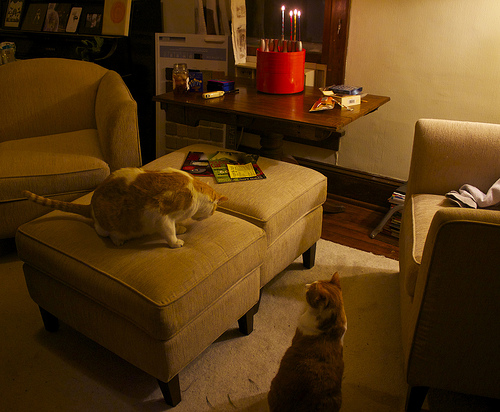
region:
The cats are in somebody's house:
[12, 9, 486, 399]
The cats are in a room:
[19, 11, 484, 389]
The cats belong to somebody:
[9, 20, 494, 393]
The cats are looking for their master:
[28, 8, 496, 388]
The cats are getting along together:
[16, 15, 484, 406]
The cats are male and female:
[14, 10, 486, 395]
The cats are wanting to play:
[3, 11, 498, 407]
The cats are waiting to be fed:
[14, 15, 466, 394]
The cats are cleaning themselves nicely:
[20, 34, 455, 410]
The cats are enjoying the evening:
[25, 24, 453, 409]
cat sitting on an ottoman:
[10, 137, 275, 408]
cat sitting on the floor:
[247, 246, 369, 410]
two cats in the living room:
[12, 103, 439, 410]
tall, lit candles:
[271, 3, 312, 43]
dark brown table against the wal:
[152, 38, 394, 188]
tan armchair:
[4, 45, 164, 280]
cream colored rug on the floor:
[3, 153, 438, 408]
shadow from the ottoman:
[37, 330, 144, 400]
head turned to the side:
[290, 268, 361, 326]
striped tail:
[15, 176, 99, 232]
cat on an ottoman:
[57, 151, 248, 302]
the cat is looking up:
[265, 258, 367, 410]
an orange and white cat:
[20, 168, 225, 249]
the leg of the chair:
[161, 376, 184, 405]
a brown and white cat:
[278, 278, 349, 408]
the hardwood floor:
[340, 203, 366, 240]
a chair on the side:
[408, 113, 495, 380]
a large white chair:
[7, 60, 146, 192]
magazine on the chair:
[185, 148, 270, 181]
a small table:
[167, 71, 384, 131]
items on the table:
[169, 67, 229, 98]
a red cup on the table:
[255, 48, 310, 93]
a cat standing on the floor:
[269, 275, 350, 410]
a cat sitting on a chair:
[18, 165, 225, 243]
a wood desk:
[164, 68, 397, 143]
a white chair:
[403, 112, 487, 380]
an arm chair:
[3, 60, 152, 203]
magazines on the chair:
[186, 148, 267, 185]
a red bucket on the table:
[256, 41, 303, 91]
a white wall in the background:
[389, 50, 492, 83]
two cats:
[89, 154, 362, 409]